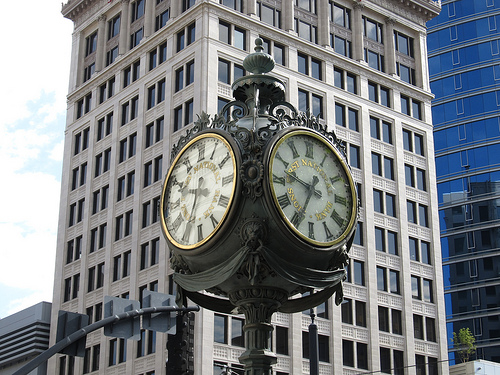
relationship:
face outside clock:
[253, 115, 406, 259] [268, 114, 370, 274]